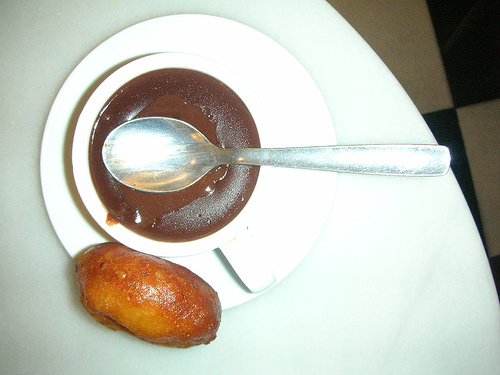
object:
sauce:
[86, 67, 262, 244]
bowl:
[71, 52, 275, 259]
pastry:
[71, 241, 219, 349]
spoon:
[102, 115, 450, 193]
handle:
[251, 144, 452, 176]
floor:
[424, 1, 500, 108]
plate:
[36, 12, 337, 315]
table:
[0, 0, 500, 375]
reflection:
[411, 154, 442, 172]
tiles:
[426, 0, 500, 108]